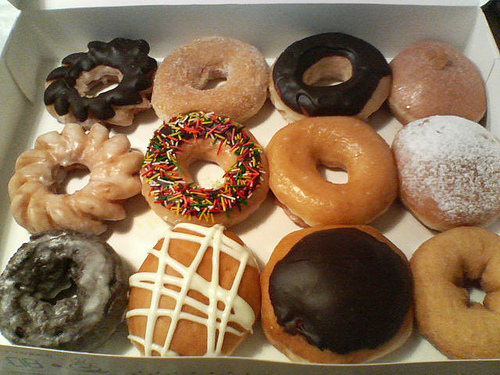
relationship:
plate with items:
[157, 5, 301, 44] [103, 40, 362, 198]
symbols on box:
[23, 338, 94, 370] [42, 12, 498, 109]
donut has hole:
[289, 130, 434, 216] [304, 153, 352, 186]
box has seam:
[42, 12, 498, 109] [0, 57, 35, 108]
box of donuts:
[42, 12, 498, 109] [46, 56, 400, 263]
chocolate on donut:
[279, 49, 317, 117] [294, 28, 411, 105]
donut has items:
[412, 118, 477, 204] [8, 38, 393, 234]